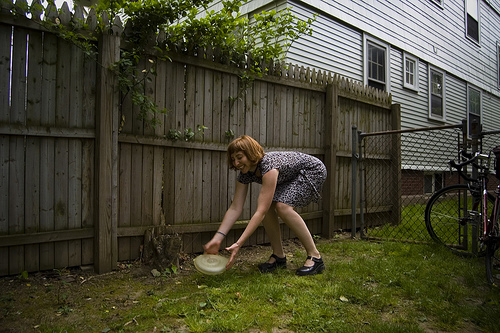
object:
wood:
[57, 4, 71, 271]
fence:
[0, 1, 401, 276]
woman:
[201, 134, 327, 277]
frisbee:
[193, 254, 229, 276]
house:
[241, 0, 500, 201]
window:
[426, 66, 443, 118]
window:
[364, 37, 389, 83]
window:
[403, 56, 416, 86]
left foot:
[295, 256, 329, 276]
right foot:
[257, 255, 287, 272]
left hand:
[225, 243, 239, 272]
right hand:
[203, 242, 221, 255]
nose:
[234, 161, 240, 166]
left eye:
[237, 156, 244, 159]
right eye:
[232, 159, 236, 162]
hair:
[226, 134, 266, 172]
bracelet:
[217, 231, 227, 238]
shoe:
[295, 256, 326, 274]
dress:
[235, 151, 328, 208]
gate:
[351, 117, 472, 251]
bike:
[424, 150, 499, 294]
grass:
[71, 291, 497, 333]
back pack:
[140, 224, 182, 271]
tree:
[35, 0, 317, 141]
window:
[464, 1, 483, 48]